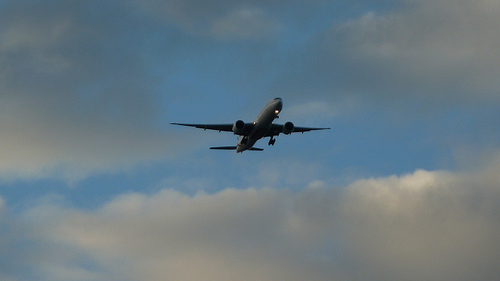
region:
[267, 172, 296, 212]
part of a cloud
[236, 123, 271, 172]
part of a plane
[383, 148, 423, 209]
part of a cloud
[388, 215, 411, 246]
part of a cloiud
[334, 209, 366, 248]
part of a cloud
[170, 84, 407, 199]
An airplane in the sky.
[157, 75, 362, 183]
A plane flying in the sky.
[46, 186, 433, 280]
The clouds is white.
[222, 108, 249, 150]
The engine of the plane.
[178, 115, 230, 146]
The wing of the plane.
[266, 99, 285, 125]
Lights on the plane.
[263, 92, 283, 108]
Nose of the plane.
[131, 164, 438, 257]
The clouds are fluffy and white.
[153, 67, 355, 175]
a plane in the air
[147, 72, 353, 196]
a plane in the sky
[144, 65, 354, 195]
a gray flying plane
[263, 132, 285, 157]
a wheel of the plane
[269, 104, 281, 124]
a light under the plane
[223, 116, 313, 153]
two jets on the plane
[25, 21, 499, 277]
white clouds in the sky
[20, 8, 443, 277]
a blue sky with clouds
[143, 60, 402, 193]
a plane heading somewhere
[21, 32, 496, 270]
a blue sky with white clouds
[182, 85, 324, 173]
plane flying in the air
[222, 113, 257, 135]
engine on bottom of plane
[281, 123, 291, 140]
engine on bottom of plane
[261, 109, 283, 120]
landing wheel of plane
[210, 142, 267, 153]
tail fins of plane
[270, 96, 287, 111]
cockpit on plane front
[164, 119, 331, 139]
wings on the plane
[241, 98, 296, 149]
large body of plane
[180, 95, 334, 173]
commercial jet in air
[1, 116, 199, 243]
blue sky with clouds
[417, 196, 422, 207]
part of a cloud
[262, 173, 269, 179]
part of the sky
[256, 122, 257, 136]
part of a plane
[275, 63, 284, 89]
tip of a plane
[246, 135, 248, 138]
part of a wing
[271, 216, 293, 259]
edge of a cloud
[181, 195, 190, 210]
part of the sky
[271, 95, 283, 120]
tip of a plane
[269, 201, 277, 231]
part of a cloud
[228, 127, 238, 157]
edge of a plane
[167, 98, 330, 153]
wing on gray airplane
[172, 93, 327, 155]
engine on airplane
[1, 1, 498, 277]
sky is blue and cloudy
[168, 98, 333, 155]
airplane is flying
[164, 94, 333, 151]
light on the bottom of the plane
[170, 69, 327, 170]
The plane flying in the sky.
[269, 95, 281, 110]
The nose of the plane.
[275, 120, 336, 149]
The left wing on the plane.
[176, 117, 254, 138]
The right wing on the plane.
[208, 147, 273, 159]
The tale of the plane.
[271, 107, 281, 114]
The light under the plane.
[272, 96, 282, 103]
The cockpit window on the plane.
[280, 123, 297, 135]
The left fuel engine.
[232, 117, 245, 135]
The right fuel engine.